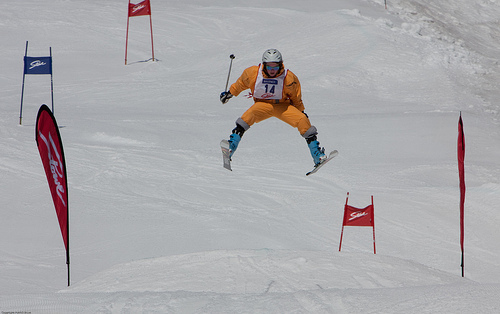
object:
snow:
[1, 0, 497, 312]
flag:
[455, 111, 469, 277]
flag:
[33, 103, 72, 288]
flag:
[126, 1, 155, 64]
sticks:
[121, 31, 132, 61]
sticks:
[14, 90, 37, 124]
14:
[263, 84, 275, 94]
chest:
[249, 73, 290, 102]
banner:
[20, 41, 56, 125]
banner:
[337, 190, 378, 253]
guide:
[220, 54, 235, 90]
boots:
[302, 125, 328, 165]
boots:
[229, 118, 251, 161]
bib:
[252, 63, 289, 99]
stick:
[367, 193, 377, 253]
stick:
[339, 190, 351, 257]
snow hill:
[1, 0, 498, 312]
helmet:
[260, 48, 283, 63]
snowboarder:
[217, 139, 333, 174]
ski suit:
[229, 64, 307, 111]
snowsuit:
[221, 62, 318, 137]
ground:
[2, 0, 494, 311]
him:
[219, 49, 327, 167]